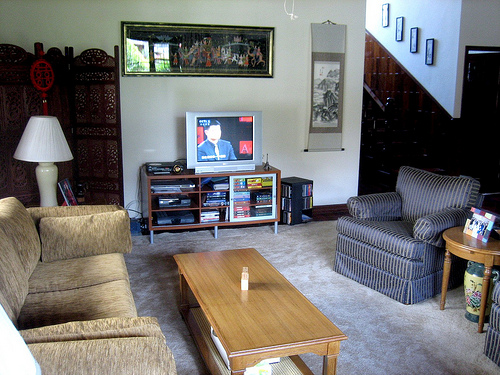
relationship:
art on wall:
[308, 17, 344, 158] [111, 4, 313, 194]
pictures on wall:
[382, 6, 463, 71] [380, 8, 476, 116]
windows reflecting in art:
[136, 33, 169, 68] [117, 11, 275, 80]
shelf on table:
[190, 296, 226, 371] [180, 245, 342, 353]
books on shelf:
[235, 187, 278, 216] [234, 191, 279, 202]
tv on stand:
[193, 117, 262, 173] [140, 159, 281, 222]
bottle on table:
[240, 266, 249, 290] [180, 245, 342, 353]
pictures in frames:
[382, 6, 463, 71] [415, 26, 429, 61]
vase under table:
[464, 252, 484, 332] [455, 223, 498, 300]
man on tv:
[203, 125, 230, 172] [193, 117, 262, 173]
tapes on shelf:
[209, 189, 227, 212] [201, 207, 235, 212]